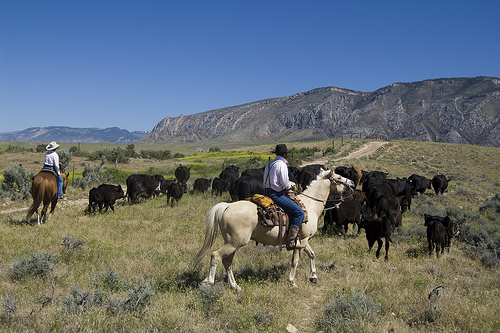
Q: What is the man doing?
A: Riding a horse.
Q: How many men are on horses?
A: Two.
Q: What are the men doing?
A: Rounding up the animals.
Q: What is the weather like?
A: Sunny and clear.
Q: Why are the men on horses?
A: Herding cattle.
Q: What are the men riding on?
A: Horses.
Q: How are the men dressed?
A: Like cowboys.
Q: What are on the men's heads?
A: Hats.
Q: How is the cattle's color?
A: Black,.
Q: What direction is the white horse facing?
A: To the right.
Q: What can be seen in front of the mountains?
A: A dirt path.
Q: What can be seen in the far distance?
A: Mountains.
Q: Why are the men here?
A: Herding cattle.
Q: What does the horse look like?
A: The horse is white.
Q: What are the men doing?
A: Riding horses.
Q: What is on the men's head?
A: Hats.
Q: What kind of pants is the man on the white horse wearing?
A: Jeans.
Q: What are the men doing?
A: Herding cows.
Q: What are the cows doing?
A: Walking.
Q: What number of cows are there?
A: Over 15.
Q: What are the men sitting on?
A: Saddles.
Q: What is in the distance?
A: Mountains.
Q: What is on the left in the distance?
A: Mountains.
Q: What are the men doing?
A: Herding the animals.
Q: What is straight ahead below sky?
A: Mountains.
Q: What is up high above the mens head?
A: Sky.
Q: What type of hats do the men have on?
A: Cowboy hats.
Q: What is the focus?
A: Cattle drive.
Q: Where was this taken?
A: Farmland.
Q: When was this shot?
A: Daytime.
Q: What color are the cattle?
A: Black.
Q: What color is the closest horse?
A: White.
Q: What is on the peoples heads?
A: Cowboy hats.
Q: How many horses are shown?
A: 2.